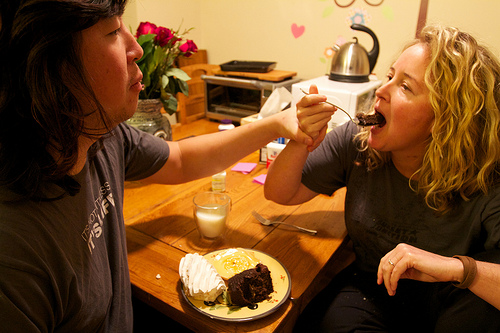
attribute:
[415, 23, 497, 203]
hair — curly, blond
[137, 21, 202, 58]
roses — red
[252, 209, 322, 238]
fork — silver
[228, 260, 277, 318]
snacks — delicious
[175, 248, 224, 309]
snacks — delicious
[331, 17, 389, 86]
kettle — black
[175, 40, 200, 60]
roses — red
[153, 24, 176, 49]
roses — red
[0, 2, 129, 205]
hair — long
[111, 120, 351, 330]
table — wood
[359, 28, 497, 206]
hair — wavy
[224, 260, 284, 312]
cake — chocolate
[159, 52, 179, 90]
roses — red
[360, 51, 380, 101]
handle — black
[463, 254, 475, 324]
wrist bands — two and brown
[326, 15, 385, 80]
kettle — silver,  silver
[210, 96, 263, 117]
tray — cookie, in back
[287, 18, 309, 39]
heart — red, paper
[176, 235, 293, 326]
plate — yellow and glass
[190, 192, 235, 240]
glass — cold, clear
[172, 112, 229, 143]
table — wooden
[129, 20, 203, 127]
bouquet — floral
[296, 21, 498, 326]
woman — blonde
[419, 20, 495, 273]
hair — long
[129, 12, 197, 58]
roses — red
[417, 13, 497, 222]
woman — blonde 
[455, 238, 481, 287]
bracelets — brown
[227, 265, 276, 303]
cake — chocolate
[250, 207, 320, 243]
fork — silver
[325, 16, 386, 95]
tea pot — silver and black, silver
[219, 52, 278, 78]
tray — small and black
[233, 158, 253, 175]
note — pink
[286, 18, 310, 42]
heart — pink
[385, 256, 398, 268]
ring — silver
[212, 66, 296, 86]
board — brown and wooden